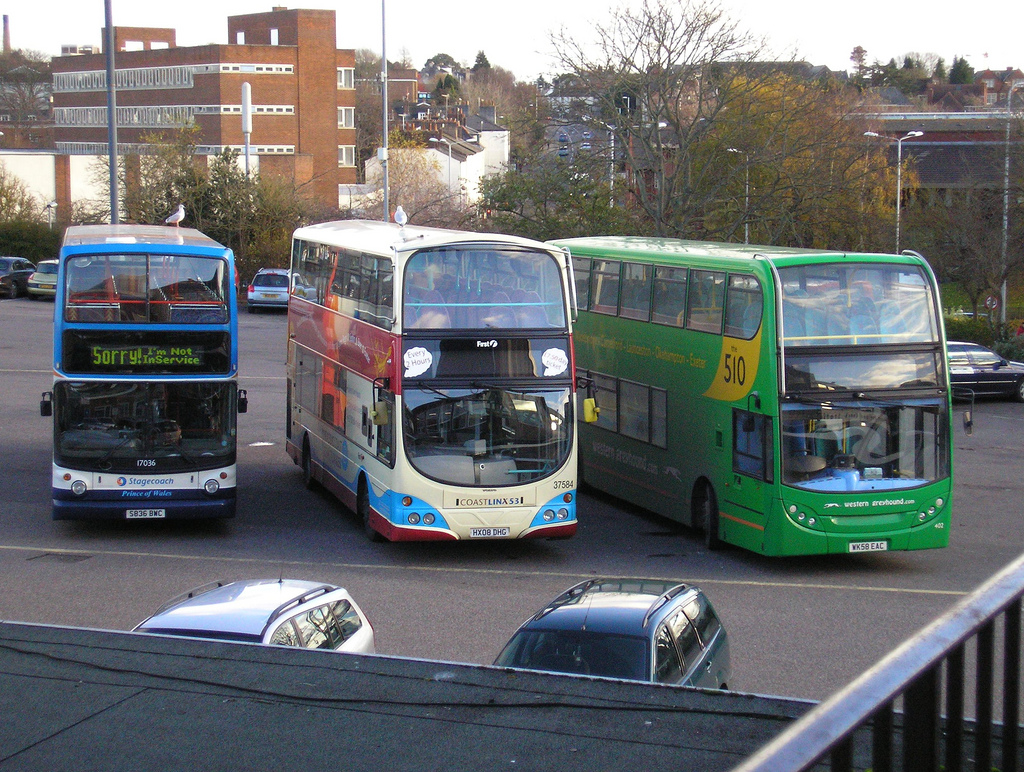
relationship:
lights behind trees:
[834, 55, 977, 257] [559, 59, 955, 327]